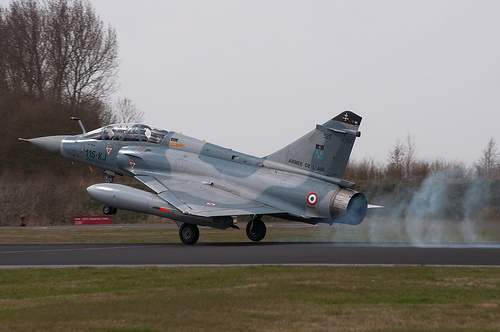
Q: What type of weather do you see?
A: It is clear.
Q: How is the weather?
A: It is clear.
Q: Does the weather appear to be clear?
A: Yes, it is clear.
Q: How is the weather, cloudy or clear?
A: It is clear.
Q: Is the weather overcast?
A: No, it is clear.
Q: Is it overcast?
A: No, it is clear.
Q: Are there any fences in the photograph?
A: No, there are no fences.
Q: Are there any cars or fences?
A: No, there are no fences or cars.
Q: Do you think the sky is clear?
A: Yes, the sky is clear.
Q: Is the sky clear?
A: Yes, the sky is clear.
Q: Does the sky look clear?
A: Yes, the sky is clear.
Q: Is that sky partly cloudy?
A: No, the sky is clear.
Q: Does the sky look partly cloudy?
A: No, the sky is clear.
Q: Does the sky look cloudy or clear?
A: The sky is clear.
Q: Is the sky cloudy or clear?
A: The sky is clear.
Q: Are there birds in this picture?
A: No, there are no birds.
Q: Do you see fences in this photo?
A: No, there are no fences.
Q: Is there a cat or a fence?
A: No, there are no fences or cats.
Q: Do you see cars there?
A: No, there are no cars.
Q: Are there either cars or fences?
A: No, there are no cars or fences.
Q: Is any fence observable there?
A: No, there are no fences.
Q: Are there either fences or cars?
A: No, there are no fences or cars.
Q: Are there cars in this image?
A: No, there are no cars.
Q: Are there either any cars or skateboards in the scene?
A: No, there are no cars or skateboards.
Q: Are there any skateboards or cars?
A: No, there are no cars or skateboards.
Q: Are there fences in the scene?
A: No, there are no fences.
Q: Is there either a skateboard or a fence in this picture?
A: No, there are no fences or skateboards.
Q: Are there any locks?
A: No, there are no locks.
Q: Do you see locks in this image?
A: No, there are no locks.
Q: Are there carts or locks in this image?
A: No, there are no locks or carts.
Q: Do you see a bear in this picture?
A: No, there are no bears.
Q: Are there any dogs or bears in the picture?
A: No, there are no bears or dogs.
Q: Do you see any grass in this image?
A: Yes, there is grass.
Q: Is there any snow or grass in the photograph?
A: Yes, there is grass.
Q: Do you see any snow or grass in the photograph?
A: Yes, there is grass.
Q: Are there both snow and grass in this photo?
A: No, there is grass but no snow.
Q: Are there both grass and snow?
A: No, there is grass but no snow.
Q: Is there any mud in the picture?
A: No, there is no mud.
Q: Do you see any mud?
A: No, there is no mud.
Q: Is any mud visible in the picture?
A: No, there is no mud.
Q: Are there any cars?
A: No, there are no cars.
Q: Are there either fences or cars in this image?
A: No, there are no cars or fences.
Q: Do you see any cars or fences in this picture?
A: No, there are no cars or fences.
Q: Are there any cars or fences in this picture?
A: No, there are no cars or fences.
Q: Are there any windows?
A: Yes, there is a window.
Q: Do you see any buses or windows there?
A: Yes, there is a window.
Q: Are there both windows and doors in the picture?
A: No, there is a window but no doors.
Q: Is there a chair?
A: No, there are no chairs.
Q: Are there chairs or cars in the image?
A: No, there are no chairs or cars.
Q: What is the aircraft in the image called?
A: The aircraft is a jet.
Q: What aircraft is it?
A: The aircraft is a jet.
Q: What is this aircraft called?
A: This is a jet.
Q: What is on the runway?
A: The jet is on the runway.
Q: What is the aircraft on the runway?
A: The aircraft is a jet.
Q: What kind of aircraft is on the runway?
A: The aircraft is a jet.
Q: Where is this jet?
A: The jet is on the runway.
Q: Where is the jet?
A: The jet is on the runway.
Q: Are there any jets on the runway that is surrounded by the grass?
A: Yes, there is a jet on the runway.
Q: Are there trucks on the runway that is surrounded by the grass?
A: No, there is a jet on the runway.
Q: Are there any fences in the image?
A: No, there are no fences.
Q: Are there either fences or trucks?
A: No, there are no fences or trucks.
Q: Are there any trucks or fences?
A: No, there are no fences or trucks.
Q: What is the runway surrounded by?
A: The runway is surrounded by the grass.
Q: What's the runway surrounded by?
A: The runway is surrounded by the grass.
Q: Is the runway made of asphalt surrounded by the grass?
A: Yes, the runway is surrounded by the grass.